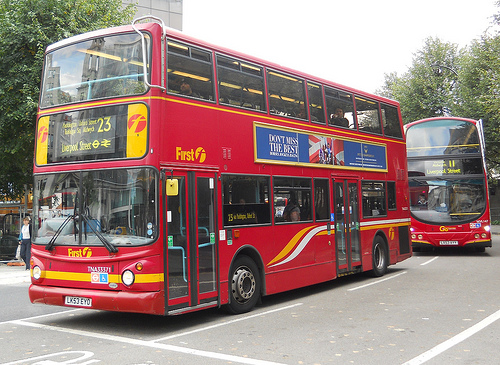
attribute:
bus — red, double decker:
[31, 20, 416, 314]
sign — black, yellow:
[46, 107, 124, 164]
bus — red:
[7, 18, 432, 343]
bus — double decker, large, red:
[57, 35, 408, 292]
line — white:
[446, 315, 481, 349]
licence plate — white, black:
[437, 239, 458, 245]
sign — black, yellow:
[54, 113, 117, 155]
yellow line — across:
[32, 262, 158, 292]